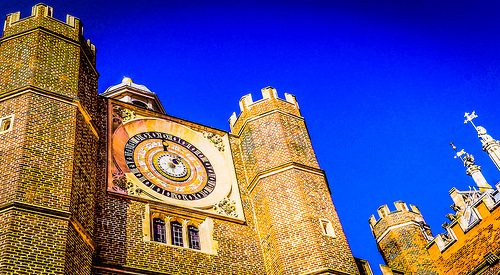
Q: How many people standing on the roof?
A: Zero.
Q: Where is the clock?
A: On the wall.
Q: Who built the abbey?
A: Construction workers.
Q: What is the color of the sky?
A: Blue.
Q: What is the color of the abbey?
A: Gold.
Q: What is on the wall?
A: A clock.